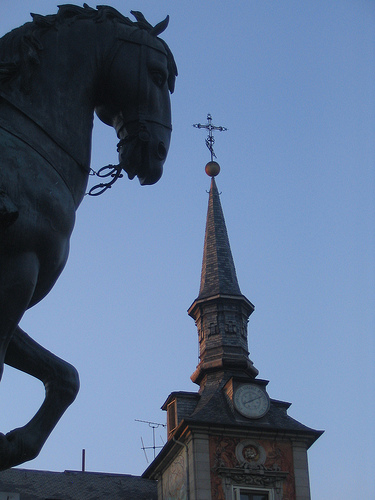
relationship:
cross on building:
[183, 105, 235, 161] [200, 185, 290, 498]